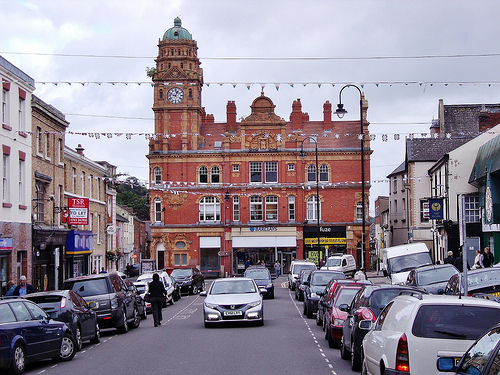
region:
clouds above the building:
[258, 18, 341, 51]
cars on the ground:
[294, 244, 415, 346]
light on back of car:
[383, 325, 427, 374]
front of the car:
[199, 284, 262, 336]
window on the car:
[202, 274, 257, 301]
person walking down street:
[127, 268, 179, 330]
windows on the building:
[226, 188, 291, 228]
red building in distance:
[178, 130, 274, 202]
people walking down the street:
[11, 256, 51, 299]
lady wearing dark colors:
[126, 261, 173, 325]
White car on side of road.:
[373, 318, 459, 370]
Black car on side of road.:
[337, 293, 388, 349]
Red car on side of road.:
[331, 285, 353, 333]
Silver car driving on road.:
[208, 274, 273, 355]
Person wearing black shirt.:
[148, 280, 166, 292]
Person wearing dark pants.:
[146, 292, 174, 320]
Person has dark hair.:
[148, 269, 164, 281]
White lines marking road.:
[296, 299, 315, 363]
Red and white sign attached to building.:
[58, 190, 120, 260]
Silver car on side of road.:
[81, 262, 148, 365]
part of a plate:
[217, 304, 254, 314]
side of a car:
[341, 297, 401, 360]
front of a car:
[200, 282, 245, 321]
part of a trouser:
[145, 290, 165, 315]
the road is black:
[157, 331, 283, 367]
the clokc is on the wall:
[157, 85, 187, 111]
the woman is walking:
[145, 269, 172, 334]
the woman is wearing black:
[147, 267, 172, 326]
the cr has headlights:
[204, 300, 268, 313]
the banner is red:
[50, 195, 98, 230]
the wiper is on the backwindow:
[429, 324, 470, 347]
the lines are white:
[307, 340, 342, 370]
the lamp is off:
[322, 97, 354, 123]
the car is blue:
[2, 291, 76, 363]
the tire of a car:
[56, 336, 74, 357]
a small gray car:
[200, 275, 267, 325]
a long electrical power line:
[0, 45, 495, 65]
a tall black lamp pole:
[335, 85, 371, 272]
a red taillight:
[390, 335, 410, 372]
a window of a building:
[260, 160, 275, 182]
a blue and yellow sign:
[420, 192, 440, 217]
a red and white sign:
[65, 197, 92, 226]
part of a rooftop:
[405, 137, 468, 158]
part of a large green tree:
[111, 175, 150, 217]